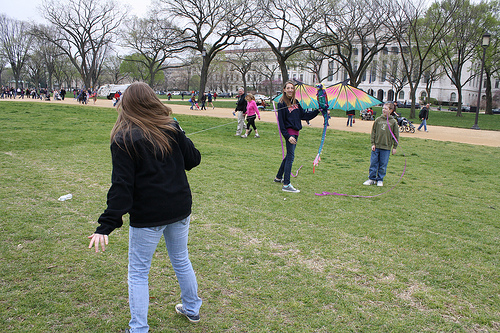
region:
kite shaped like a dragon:
[270, 77, 383, 169]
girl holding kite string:
[85, 80, 200, 332]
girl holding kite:
[269, 80, 329, 195]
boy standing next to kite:
[362, 99, 400, 186]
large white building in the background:
[169, 26, 497, 111]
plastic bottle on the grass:
[57, 191, 72, 202]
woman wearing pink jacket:
[245, 91, 260, 138]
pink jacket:
[243, 99, 260, 119]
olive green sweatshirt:
[370, 113, 398, 150]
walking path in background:
[2, 94, 498, 149]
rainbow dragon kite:
[271, 75, 388, 170]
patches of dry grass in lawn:
[240, 234, 426, 328]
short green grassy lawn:
[342, 193, 493, 278]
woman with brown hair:
[112, 74, 175, 159]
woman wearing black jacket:
[103, 83, 184, 238]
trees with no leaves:
[30, 10, 362, 86]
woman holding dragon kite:
[273, 79, 338, 136]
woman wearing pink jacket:
[235, 90, 258, 132]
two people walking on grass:
[230, 87, 262, 137]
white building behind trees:
[345, 26, 468, 86]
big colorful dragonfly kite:
[293, 84, 355, 171]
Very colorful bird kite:
[254, 68, 381, 119]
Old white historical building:
[182, 4, 484, 112]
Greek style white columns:
[348, 40, 454, 90]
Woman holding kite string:
[98, 84, 196, 327]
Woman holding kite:
[273, 68, 305, 209]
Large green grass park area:
[7, 100, 462, 316]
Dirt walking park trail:
[91, 49, 496, 150]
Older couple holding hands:
[228, 77, 256, 135]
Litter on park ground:
[51, 189, 75, 216]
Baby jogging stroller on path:
[397, 110, 417, 139]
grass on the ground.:
[380, 231, 412, 249]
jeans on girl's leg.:
[132, 245, 146, 309]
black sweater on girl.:
[150, 167, 179, 200]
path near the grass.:
[450, 129, 489, 137]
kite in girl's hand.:
[323, 90, 353, 100]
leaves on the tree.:
[127, 62, 147, 73]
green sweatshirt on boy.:
[375, 123, 387, 137]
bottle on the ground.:
[57, 188, 71, 207]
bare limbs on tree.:
[297, 10, 321, 26]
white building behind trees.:
[429, 82, 449, 96]